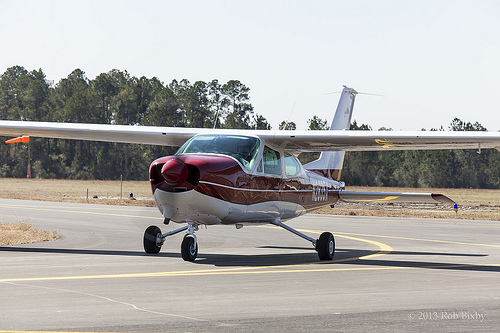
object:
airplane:
[0, 85, 500, 262]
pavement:
[0, 196, 500, 333]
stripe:
[0, 204, 500, 286]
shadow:
[0, 245, 500, 273]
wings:
[0, 118, 197, 148]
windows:
[257, 157, 264, 173]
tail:
[301, 84, 359, 183]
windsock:
[5, 134, 32, 144]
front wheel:
[181, 235, 199, 262]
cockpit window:
[174, 134, 261, 171]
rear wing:
[337, 190, 458, 205]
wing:
[260, 128, 500, 155]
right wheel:
[143, 225, 162, 254]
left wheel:
[318, 232, 336, 261]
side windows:
[263, 145, 282, 176]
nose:
[160, 159, 187, 184]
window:
[283, 151, 299, 177]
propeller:
[147, 155, 203, 195]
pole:
[26, 136, 33, 180]